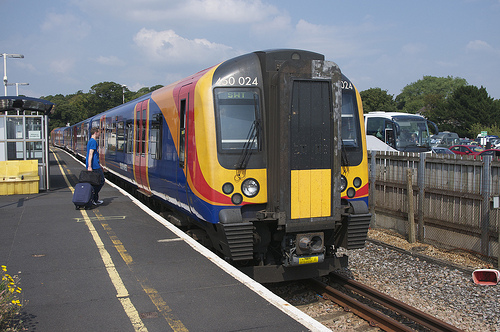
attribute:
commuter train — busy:
[50, 44, 372, 272]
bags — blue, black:
[55, 156, 147, 220]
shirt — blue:
[82, 137, 131, 178]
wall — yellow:
[2, 151, 59, 208]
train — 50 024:
[46, 38, 380, 300]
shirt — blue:
[84, 138, 99, 165]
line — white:
[154, 211, 260, 303]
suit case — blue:
[73, 175, 100, 207]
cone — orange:
[467, 263, 498, 291]